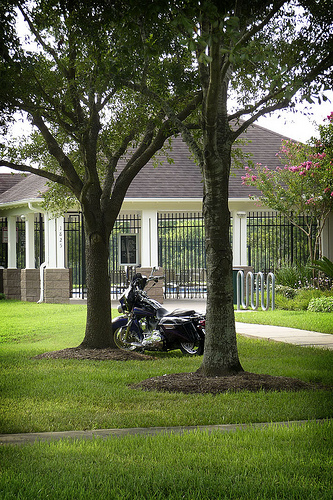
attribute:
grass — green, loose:
[8, 298, 229, 486]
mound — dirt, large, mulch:
[135, 360, 305, 408]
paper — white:
[142, 366, 182, 400]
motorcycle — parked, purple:
[117, 263, 212, 353]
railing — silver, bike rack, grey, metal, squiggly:
[222, 264, 280, 315]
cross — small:
[82, 230, 113, 250]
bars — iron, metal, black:
[63, 210, 318, 305]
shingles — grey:
[150, 158, 218, 203]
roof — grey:
[0, 96, 332, 202]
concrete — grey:
[165, 292, 332, 363]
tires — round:
[115, 317, 216, 357]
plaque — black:
[119, 230, 148, 268]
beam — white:
[49, 221, 67, 274]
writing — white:
[120, 234, 136, 265]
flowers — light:
[292, 268, 330, 289]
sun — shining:
[5, 298, 102, 347]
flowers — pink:
[243, 147, 331, 192]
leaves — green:
[42, 14, 249, 98]